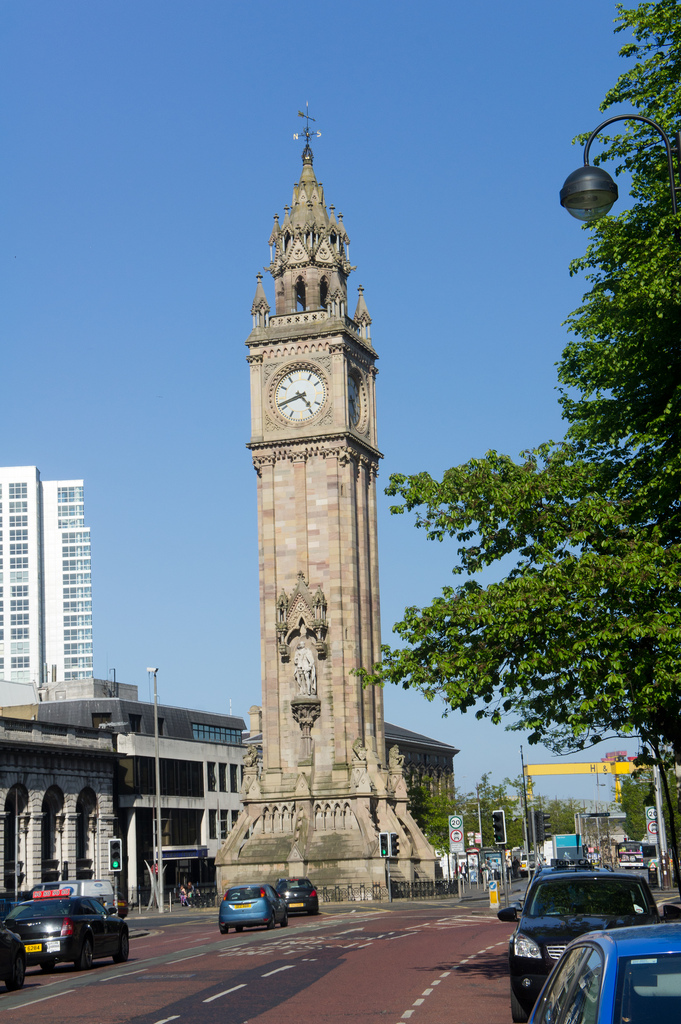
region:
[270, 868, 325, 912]
Small black car driving on road.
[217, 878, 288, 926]
Small blue car driving on road.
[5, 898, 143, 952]
Black car driving on road.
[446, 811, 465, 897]
Signs connected to gray pole.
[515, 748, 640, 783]
Yellow sign attached to poles.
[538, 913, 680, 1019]
Blue car driving on road.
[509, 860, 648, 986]
Black vehicle driving on road.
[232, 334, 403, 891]
Large clock tower near building.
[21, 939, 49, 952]
Yellow plate on car.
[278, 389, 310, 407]
Hands on a clock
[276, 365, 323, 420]
A large white clock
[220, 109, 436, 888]
A large stone clocktower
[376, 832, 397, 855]
Traffic lights in the street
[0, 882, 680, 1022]
A multi-lane city street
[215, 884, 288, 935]
A small blue car in the street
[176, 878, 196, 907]
People on the sidewalk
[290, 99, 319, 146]
A weathervane at the top of the clocktower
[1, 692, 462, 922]
Buildings by the street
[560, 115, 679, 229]
the street light pole is black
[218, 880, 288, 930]
he car is blue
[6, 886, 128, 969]
the car is black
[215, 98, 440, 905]
the clock tower is tall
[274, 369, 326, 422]
the clock is round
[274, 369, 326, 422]
the black hands on the clock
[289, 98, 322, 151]
the weather vane is made of metal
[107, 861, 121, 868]
the street light is green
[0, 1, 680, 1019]
the blue sky above the cars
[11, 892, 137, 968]
A car in the street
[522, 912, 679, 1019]
A blue car in the street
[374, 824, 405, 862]
A stoplight in the city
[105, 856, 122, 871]
A green light on a stoplight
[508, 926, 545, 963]
A headlight on a truck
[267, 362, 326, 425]
A clock on a tower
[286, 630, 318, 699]
A statue on a clock tower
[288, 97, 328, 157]
A weather vane on a tower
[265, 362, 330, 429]
clock on the tower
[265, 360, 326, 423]
black and white clock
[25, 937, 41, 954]
yellow and black license plate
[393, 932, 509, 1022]
white dotted line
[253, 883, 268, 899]
red light on the back of the vehicle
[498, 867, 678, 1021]
black SUV parked on the side of the road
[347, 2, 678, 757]
the leaves on the tree are dark green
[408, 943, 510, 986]
shadow on the street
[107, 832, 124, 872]
traffic light is shining green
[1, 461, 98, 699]
tall white building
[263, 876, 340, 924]
a car that is dark blue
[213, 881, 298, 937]
a car that is light blue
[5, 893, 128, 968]
a car that is black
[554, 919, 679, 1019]
a car that is sky blue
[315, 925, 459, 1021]
a road that is red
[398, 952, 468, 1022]
a bunch of dotted line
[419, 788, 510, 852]
a tree that is green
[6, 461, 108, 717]
a building that is white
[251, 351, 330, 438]
black and white clock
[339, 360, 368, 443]
black and white clock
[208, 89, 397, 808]
tall tan and gray clock tower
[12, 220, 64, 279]
blue sky with no clouds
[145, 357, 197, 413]
blue sky with no clouds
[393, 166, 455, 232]
blue sky with no clouds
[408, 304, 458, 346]
blue sky with no clouds